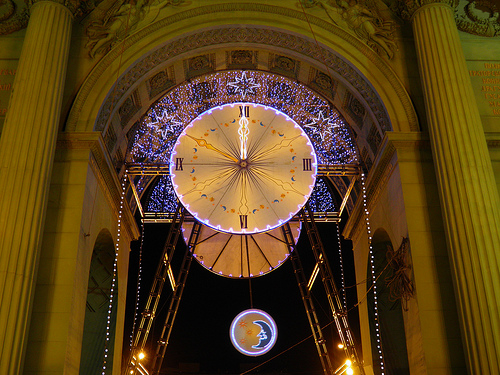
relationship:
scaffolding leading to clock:
[119, 203, 368, 375] [169, 102, 319, 234]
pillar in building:
[401, 1, 499, 374] [0, 0, 499, 374]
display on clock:
[131, 67, 361, 165] [169, 102, 319, 234]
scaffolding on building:
[119, 203, 368, 375] [0, 0, 499, 374]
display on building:
[131, 67, 361, 165] [0, 0, 499, 374]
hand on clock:
[184, 133, 239, 164] [169, 102, 319, 234]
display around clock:
[131, 67, 361, 165] [169, 102, 319, 234]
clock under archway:
[169, 102, 319, 234] [62, 24, 429, 373]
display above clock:
[131, 67, 361, 165] [169, 102, 319, 234]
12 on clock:
[237, 104, 251, 120] [169, 102, 319, 234]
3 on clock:
[300, 157, 315, 173] [169, 102, 319, 234]